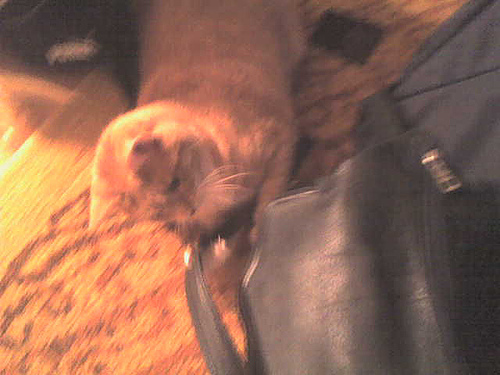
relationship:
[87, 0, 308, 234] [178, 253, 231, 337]
cat playing with strap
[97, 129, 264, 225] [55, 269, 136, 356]
cat on floor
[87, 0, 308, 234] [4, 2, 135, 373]
cat on floor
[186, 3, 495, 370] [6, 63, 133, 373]
purse on floor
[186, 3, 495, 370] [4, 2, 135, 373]
purse on floor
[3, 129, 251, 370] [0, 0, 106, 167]
carpet on floor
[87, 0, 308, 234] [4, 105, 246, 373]
cat on rug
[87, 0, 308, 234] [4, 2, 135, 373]
cat laying on floor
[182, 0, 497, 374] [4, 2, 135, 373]
bag on floor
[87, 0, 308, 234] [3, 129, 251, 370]
cat laying on carpet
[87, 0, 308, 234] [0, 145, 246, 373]
cat laying on carpet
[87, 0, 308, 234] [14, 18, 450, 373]
cat laying on carpet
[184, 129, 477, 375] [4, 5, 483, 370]
purse on floor